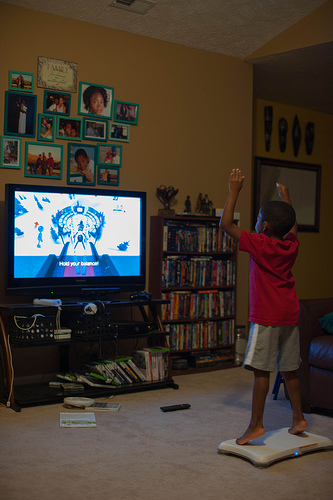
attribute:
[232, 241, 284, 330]
shirt — red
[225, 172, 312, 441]
boy — playing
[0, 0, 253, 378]
wall — yellow